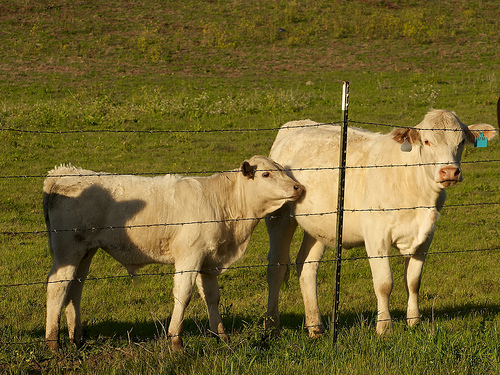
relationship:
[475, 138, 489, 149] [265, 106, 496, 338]
tag on cow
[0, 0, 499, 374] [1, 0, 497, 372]
grass on field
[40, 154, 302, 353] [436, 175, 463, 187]
cow has mouth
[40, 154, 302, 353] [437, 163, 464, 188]
cow has nose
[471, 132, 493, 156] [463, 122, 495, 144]
tag on ear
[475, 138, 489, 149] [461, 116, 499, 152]
tag on ear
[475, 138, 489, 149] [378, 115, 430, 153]
tag on ear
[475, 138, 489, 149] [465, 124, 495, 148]
tag on ear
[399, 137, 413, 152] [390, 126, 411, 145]
tag on ear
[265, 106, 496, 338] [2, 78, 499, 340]
cow behind fence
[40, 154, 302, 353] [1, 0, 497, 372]
cow in field